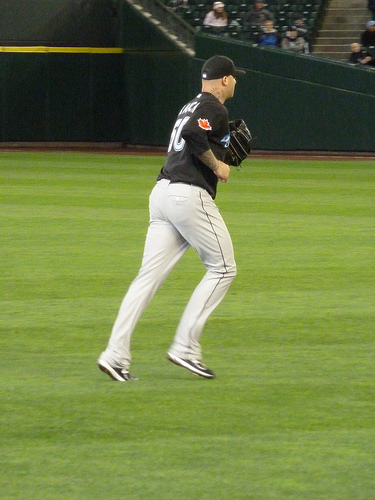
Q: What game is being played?
A: Baseball.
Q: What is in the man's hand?
A: A mitt.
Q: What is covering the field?
A: Grass.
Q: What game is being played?
A: Baseball.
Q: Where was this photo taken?
A: At a baseball stadium.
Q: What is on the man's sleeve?
A: A leaf.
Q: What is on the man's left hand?
A: A baseball glove.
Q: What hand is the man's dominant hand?
A: His right hand.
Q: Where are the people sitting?
A: In the stands.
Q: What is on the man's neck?
A: A tattoo.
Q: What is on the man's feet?
A: Baseball cleats.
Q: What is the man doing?
A: Running.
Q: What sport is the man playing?
A: Baseball.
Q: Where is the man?
A: Baseball field.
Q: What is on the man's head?
A: Baseball cap.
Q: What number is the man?
A: 50.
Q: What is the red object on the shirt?
A: Maple leaf.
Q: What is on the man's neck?
A: Tattoo.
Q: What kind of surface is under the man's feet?
A: Grass.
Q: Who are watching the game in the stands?
A: Fans.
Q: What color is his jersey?
A: Black.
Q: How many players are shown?
A: One.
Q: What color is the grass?
A: Green.